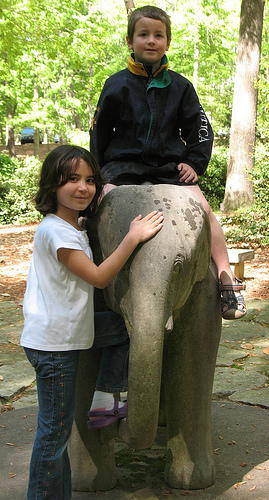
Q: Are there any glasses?
A: No, there are no glasses.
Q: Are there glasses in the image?
A: No, there are no glasses.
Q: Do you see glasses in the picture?
A: No, there are no glasses.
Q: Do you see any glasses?
A: No, there are no glasses.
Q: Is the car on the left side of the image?
A: Yes, the car is on the left of the image.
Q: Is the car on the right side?
A: No, the car is on the left of the image.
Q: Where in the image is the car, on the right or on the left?
A: The car is on the left of the image.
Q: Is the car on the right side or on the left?
A: The car is on the left of the image.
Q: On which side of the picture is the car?
A: The car is on the left of the image.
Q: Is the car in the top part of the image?
A: Yes, the car is in the top of the image.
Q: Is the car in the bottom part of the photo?
A: No, the car is in the top of the image.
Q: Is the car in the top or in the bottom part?
A: The car is in the top of the image.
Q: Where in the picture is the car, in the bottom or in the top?
A: The car is in the top of the image.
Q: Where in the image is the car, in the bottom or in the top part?
A: The car is in the top of the image.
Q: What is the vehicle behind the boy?
A: The vehicle is a car.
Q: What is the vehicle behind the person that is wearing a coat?
A: The vehicle is a car.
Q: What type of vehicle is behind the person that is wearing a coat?
A: The vehicle is a car.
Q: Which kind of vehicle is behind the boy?
A: The vehicle is a car.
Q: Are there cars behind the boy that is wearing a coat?
A: Yes, there is a car behind the boy.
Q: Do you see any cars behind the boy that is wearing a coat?
A: Yes, there is a car behind the boy.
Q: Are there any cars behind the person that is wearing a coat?
A: Yes, there is a car behind the boy.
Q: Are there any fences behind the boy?
A: No, there is a car behind the boy.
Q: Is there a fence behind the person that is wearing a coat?
A: No, there is a car behind the boy.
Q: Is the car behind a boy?
A: Yes, the car is behind a boy.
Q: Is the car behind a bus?
A: No, the car is behind a boy.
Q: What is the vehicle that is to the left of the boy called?
A: The vehicle is a car.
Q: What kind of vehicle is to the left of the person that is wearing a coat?
A: The vehicle is a car.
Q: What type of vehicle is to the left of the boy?
A: The vehicle is a car.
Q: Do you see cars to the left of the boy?
A: Yes, there is a car to the left of the boy.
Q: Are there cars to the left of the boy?
A: Yes, there is a car to the left of the boy.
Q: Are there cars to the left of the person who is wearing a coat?
A: Yes, there is a car to the left of the boy.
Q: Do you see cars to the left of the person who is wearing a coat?
A: Yes, there is a car to the left of the boy.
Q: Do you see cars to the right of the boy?
A: No, the car is to the left of the boy.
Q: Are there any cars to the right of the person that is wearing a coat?
A: No, the car is to the left of the boy.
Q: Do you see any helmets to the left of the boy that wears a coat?
A: No, there is a car to the left of the boy.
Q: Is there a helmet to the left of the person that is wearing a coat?
A: No, there is a car to the left of the boy.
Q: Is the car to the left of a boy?
A: Yes, the car is to the left of a boy.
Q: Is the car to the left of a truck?
A: No, the car is to the left of a boy.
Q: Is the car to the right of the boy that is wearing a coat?
A: No, the car is to the left of the boy.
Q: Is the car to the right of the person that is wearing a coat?
A: No, the car is to the left of the boy.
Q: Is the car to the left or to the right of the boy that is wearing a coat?
A: The car is to the left of the boy.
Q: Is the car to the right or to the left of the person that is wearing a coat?
A: The car is to the left of the boy.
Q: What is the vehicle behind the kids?
A: The vehicle is a car.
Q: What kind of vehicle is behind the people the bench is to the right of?
A: The vehicle is a car.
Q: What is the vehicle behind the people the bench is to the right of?
A: The vehicle is a car.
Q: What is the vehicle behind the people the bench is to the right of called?
A: The vehicle is a car.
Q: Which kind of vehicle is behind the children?
A: The vehicle is a car.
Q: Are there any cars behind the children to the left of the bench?
A: Yes, there is a car behind the children.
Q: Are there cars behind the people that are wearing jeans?
A: Yes, there is a car behind the children.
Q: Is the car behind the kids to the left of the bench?
A: Yes, the car is behind the children.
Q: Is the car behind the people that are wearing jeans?
A: Yes, the car is behind the children.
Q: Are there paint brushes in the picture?
A: No, there are no paint brushes.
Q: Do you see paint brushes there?
A: No, there are no paint brushes.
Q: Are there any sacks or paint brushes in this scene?
A: No, there are no paint brushes or sacks.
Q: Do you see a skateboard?
A: No, there are no skateboards.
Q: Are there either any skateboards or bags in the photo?
A: No, there are no skateboards or bags.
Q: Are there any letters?
A: Yes, there are letters.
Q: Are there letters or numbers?
A: Yes, there are letters.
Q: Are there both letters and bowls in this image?
A: No, there are letters but no bowls.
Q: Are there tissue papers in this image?
A: No, there are no tissue papers.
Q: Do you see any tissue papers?
A: No, there are no tissue papers.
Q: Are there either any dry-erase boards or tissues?
A: No, there are no tissues or dry-erase boards.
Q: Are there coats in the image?
A: Yes, there is a coat.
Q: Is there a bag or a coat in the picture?
A: Yes, there is a coat.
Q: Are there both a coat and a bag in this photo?
A: No, there is a coat but no bags.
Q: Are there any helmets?
A: No, there are no helmets.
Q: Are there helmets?
A: No, there are no helmets.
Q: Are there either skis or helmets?
A: No, there are no helmets or skis.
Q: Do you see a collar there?
A: Yes, there is a collar.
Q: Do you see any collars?
A: Yes, there is a collar.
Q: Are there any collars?
A: Yes, there is a collar.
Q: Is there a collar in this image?
A: Yes, there is a collar.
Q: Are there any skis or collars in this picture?
A: Yes, there is a collar.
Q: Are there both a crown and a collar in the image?
A: No, there is a collar but no crowns.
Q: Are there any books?
A: No, there are no books.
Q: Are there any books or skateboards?
A: No, there are no books or skateboards.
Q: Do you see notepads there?
A: No, there are no notepads.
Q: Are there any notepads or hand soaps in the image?
A: No, there are no notepads or hand soaps.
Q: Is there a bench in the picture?
A: Yes, there is a bench.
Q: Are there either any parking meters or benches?
A: Yes, there is a bench.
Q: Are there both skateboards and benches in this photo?
A: No, there is a bench but no skateboards.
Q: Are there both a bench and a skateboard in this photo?
A: No, there is a bench but no skateboards.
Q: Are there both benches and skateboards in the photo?
A: No, there is a bench but no skateboards.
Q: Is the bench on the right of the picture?
A: Yes, the bench is on the right of the image.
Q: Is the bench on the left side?
A: No, the bench is on the right of the image.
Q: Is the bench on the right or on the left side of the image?
A: The bench is on the right of the image.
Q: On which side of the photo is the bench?
A: The bench is on the right of the image.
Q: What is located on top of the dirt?
A: The bench is on top of the dirt.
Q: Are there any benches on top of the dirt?
A: Yes, there is a bench on top of the dirt.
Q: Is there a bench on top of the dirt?
A: Yes, there is a bench on top of the dirt.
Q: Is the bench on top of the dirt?
A: Yes, the bench is on top of the dirt.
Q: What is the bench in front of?
A: The bench is in front of the tree.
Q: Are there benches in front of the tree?
A: Yes, there is a bench in front of the tree.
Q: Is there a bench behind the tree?
A: No, the bench is in front of the tree.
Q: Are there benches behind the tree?
A: No, the bench is in front of the tree.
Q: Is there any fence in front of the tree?
A: No, there is a bench in front of the tree.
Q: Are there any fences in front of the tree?
A: No, there is a bench in front of the tree.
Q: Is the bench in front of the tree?
A: Yes, the bench is in front of the tree.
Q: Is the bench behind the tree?
A: No, the bench is in front of the tree.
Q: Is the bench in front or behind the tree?
A: The bench is in front of the tree.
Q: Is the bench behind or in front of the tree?
A: The bench is in front of the tree.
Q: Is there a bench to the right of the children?
A: Yes, there is a bench to the right of the children.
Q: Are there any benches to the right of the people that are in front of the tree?
A: Yes, there is a bench to the right of the children.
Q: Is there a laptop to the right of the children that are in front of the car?
A: No, there is a bench to the right of the children.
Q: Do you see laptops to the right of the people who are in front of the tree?
A: No, there is a bench to the right of the children.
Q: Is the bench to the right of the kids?
A: Yes, the bench is to the right of the kids.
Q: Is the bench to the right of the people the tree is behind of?
A: Yes, the bench is to the right of the kids.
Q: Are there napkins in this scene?
A: No, there are no napkins.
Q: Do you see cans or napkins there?
A: No, there are no napkins or cans.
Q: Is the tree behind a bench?
A: Yes, the tree is behind a bench.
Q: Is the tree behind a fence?
A: No, the tree is behind a bench.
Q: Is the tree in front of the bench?
A: No, the tree is behind the bench.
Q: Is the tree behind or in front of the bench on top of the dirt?
A: The tree is behind the bench.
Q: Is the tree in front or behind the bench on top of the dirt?
A: The tree is behind the bench.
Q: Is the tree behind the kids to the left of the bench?
A: Yes, the tree is behind the kids.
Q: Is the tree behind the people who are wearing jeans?
A: Yes, the tree is behind the kids.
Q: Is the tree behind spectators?
A: No, the tree is behind the kids.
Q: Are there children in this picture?
A: Yes, there are children.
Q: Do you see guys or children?
A: Yes, there are children.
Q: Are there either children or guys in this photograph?
A: Yes, there are children.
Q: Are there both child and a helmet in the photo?
A: No, there are children but no helmets.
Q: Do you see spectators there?
A: No, there are no spectators.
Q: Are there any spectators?
A: No, there are no spectators.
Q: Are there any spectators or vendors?
A: No, there are no spectators or vendors.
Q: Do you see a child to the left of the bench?
A: Yes, there are children to the left of the bench.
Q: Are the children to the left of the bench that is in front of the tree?
A: Yes, the children are to the left of the bench.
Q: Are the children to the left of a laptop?
A: No, the children are to the left of the bench.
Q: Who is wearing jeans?
A: The kids are wearing jeans.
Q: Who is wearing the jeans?
A: The kids are wearing jeans.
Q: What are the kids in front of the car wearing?
A: The children are wearing jeans.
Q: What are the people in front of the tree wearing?
A: The children are wearing jeans.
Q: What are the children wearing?
A: The children are wearing jeans.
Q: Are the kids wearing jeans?
A: Yes, the kids are wearing jeans.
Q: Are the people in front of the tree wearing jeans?
A: Yes, the kids are wearing jeans.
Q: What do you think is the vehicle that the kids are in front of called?
A: The vehicle is a car.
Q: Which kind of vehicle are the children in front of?
A: The kids are in front of the car.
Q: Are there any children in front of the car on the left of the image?
A: Yes, there are children in front of the car.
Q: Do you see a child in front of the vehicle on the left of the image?
A: Yes, there are children in front of the car.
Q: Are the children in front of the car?
A: Yes, the children are in front of the car.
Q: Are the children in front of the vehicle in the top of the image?
A: Yes, the children are in front of the car.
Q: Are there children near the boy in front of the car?
A: Yes, there are children near the boy.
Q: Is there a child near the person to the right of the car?
A: Yes, there are children near the boy.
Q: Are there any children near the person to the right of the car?
A: Yes, there are children near the boy.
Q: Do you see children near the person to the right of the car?
A: Yes, there are children near the boy.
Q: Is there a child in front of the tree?
A: Yes, there are children in front of the tree.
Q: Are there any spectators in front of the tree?
A: No, there are children in front of the tree.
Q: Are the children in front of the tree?
A: Yes, the children are in front of the tree.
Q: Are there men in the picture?
A: No, there are no men.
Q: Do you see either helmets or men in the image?
A: No, there are no men or helmets.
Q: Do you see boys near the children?
A: Yes, there is a boy near the children.